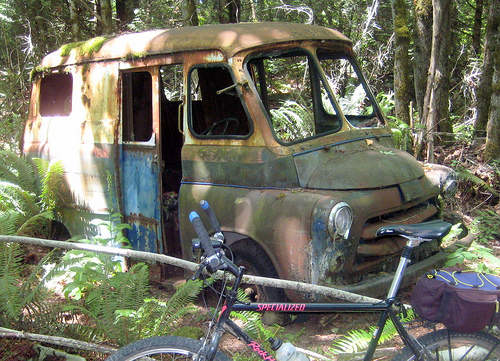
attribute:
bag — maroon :
[411, 270, 498, 324]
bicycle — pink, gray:
[107, 197, 463, 359]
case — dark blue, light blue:
[407, 259, 498, 335]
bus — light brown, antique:
[28, 17, 461, 314]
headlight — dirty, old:
[325, 191, 356, 247]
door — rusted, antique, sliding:
[118, 65, 167, 278]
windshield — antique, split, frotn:
[237, 28, 400, 182]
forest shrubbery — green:
[9, 163, 251, 359]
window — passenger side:
[243, 10, 346, 179]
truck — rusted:
[0, 0, 474, 300]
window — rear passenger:
[34, 71, 69, 128]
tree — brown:
[385, 0, 464, 212]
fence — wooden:
[9, 191, 464, 359]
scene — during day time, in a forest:
[6, 5, 490, 359]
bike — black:
[64, 182, 498, 359]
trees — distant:
[1, 0, 498, 220]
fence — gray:
[7, 199, 496, 359]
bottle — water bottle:
[248, 303, 347, 359]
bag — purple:
[352, 215, 498, 335]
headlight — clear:
[305, 191, 378, 261]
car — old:
[9, 5, 474, 295]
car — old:
[15, 25, 483, 335]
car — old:
[9, 0, 479, 338]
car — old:
[36, 29, 428, 280]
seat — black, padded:
[368, 211, 458, 241]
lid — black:
[255, 334, 288, 350]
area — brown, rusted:
[350, 183, 416, 210]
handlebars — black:
[160, 197, 248, 285]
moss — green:
[21, 33, 86, 64]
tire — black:
[131, 317, 194, 342]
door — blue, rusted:
[112, 64, 165, 252]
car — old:
[16, 17, 479, 307]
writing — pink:
[253, 298, 310, 314]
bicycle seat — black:
[372, 214, 455, 249]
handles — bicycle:
[184, 193, 230, 273]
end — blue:
[183, 209, 201, 224]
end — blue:
[199, 196, 214, 214]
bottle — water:
[264, 333, 341, 359]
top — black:
[264, 333, 284, 354]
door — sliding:
[114, 53, 164, 278]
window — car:
[176, 53, 252, 147]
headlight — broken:
[325, 200, 358, 246]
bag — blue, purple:
[405, 264, 495, 334]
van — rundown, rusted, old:
[18, 14, 483, 323]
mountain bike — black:
[111, 196, 498, 358]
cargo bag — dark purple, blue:
[409, 263, 496, 332]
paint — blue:
[120, 148, 166, 253]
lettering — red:
[250, 297, 312, 318]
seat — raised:
[377, 214, 456, 246]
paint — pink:
[252, 298, 310, 321]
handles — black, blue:
[176, 191, 246, 283]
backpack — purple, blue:
[409, 264, 498, 337]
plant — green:
[4, 165, 215, 358]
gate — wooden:
[5, 213, 412, 357]